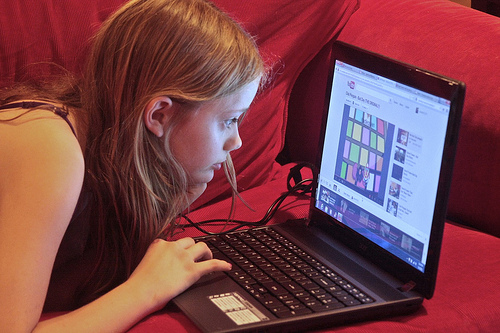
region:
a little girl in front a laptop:
[7, 4, 489, 327]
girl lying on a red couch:
[5, 4, 495, 327]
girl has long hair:
[22, 4, 267, 301]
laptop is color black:
[153, 30, 469, 332]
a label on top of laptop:
[200, 286, 270, 331]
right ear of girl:
[136, 82, 182, 143]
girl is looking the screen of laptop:
[78, 15, 465, 287]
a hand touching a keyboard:
[123, 216, 260, 320]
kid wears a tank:
[6, 0, 293, 320]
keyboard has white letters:
[194, 213, 379, 327]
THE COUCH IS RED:
[1, 0, 498, 331]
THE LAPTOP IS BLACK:
[166, 35, 468, 332]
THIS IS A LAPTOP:
[168, 34, 470, 331]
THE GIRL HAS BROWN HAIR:
[0, 0, 270, 315]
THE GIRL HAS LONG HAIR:
[0, 0, 273, 318]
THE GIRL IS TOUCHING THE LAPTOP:
[146, 35, 469, 332]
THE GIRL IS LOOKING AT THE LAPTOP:
[0, 0, 275, 331]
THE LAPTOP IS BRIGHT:
[144, 35, 469, 332]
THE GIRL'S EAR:
[136, 90, 178, 144]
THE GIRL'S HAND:
[138, 230, 235, 309]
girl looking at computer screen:
[125, 31, 433, 269]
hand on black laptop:
[169, 230, 238, 278]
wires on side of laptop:
[252, 166, 308, 224]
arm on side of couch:
[415, 12, 497, 59]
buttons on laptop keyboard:
[241, 245, 292, 280]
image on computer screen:
[338, 105, 411, 186]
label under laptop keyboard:
[207, 289, 264, 326]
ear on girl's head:
[137, 83, 182, 141]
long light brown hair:
[103, 72, 144, 219]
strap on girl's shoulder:
[10, 86, 89, 140]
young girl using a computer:
[1, 0, 263, 331]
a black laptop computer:
[173, 40, 465, 332]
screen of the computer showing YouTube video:
[314, 55, 452, 267]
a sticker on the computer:
[208, 290, 271, 325]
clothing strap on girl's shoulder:
[1, 98, 79, 146]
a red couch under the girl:
[0, 0, 499, 332]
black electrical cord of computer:
[171, 160, 318, 233]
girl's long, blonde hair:
[1, 0, 267, 288]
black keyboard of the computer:
[191, 226, 372, 318]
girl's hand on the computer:
[135, 235, 232, 300]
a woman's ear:
[142, 95, 172, 138]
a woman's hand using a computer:
[137, 236, 251, 329]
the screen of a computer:
[312, 41, 457, 282]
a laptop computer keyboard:
[192, 226, 377, 323]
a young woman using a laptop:
[2, 1, 467, 331]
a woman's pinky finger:
[196, 258, 232, 274]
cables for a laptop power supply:
[169, 171, 315, 235]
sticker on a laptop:
[205, 290, 269, 327]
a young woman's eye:
[222, 114, 237, 129]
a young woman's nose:
[224, 130, 241, 152]